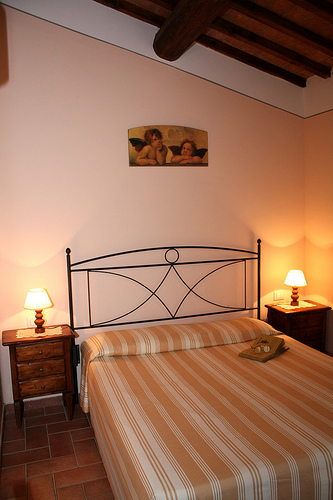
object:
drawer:
[12, 341, 65, 361]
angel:
[166, 138, 208, 165]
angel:
[129, 128, 168, 167]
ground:
[278, 100, 304, 228]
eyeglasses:
[252, 336, 270, 354]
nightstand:
[264, 300, 332, 353]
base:
[33, 309, 45, 332]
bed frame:
[63, 236, 262, 416]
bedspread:
[76, 318, 330, 500]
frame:
[63, 234, 263, 347]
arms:
[170, 154, 203, 165]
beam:
[142, 5, 329, 88]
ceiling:
[1, 2, 332, 82]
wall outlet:
[274, 289, 285, 301]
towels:
[236, 330, 289, 362]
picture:
[126, 124, 208, 168]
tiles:
[0, 406, 111, 498]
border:
[0, 1, 329, 90]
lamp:
[283, 269, 307, 306]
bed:
[63, 236, 330, 496]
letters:
[258, 338, 270, 343]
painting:
[128, 122, 209, 168]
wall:
[0, 1, 309, 411]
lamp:
[22, 283, 54, 335]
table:
[1, 327, 80, 429]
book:
[238, 334, 288, 363]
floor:
[0, 388, 114, 500]